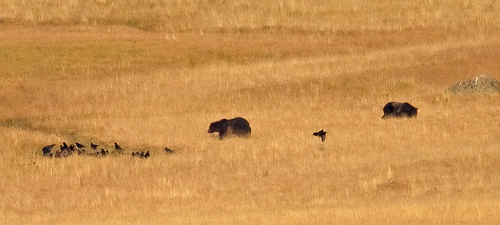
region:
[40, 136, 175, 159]
a flock of birds in a field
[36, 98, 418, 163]
bears chasing birds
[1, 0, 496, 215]
a field of brown grass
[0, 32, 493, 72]
grass is cut lower in this area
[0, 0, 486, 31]
grass is high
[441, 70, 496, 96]
a small pile of rocks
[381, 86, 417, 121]
bear is headed to the right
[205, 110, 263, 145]
bear is headed toward the birds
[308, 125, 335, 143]
bird flying away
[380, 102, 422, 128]
bear in the field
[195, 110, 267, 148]
bear in the field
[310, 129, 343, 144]
the bird is flying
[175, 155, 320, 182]
hay in the field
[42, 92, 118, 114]
weeds in the field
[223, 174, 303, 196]
he weeds are tall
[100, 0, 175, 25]
the weeds are tall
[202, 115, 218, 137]
head of the bear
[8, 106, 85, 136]
grass in the field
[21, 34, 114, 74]
grassy patch on field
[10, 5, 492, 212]
a photo during the day time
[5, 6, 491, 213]
a scene of a mostly dry grassy field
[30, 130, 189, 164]
a group of black birds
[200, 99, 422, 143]
a couple of black bears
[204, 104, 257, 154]
a bear walking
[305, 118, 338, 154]
a bird opening its wings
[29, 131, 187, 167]
some birds enjoying the day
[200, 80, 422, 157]
a couple of bears enjoying the day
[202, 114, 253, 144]
brown bear in a wheat field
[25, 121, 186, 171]
a flock of black birds on the ground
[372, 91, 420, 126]
brown bear walking on a field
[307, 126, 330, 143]
black bird flying close to the ground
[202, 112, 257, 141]
a grizzly bear walking on a field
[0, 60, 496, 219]
large field of gold grass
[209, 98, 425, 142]
two brown bears walking in opposite directions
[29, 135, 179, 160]
the flock of birds are eating something on the ground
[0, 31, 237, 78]
area of flat laying greener grass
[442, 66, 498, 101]
low laying rock in the field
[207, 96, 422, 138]
two black bears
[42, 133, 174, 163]
flock of black birds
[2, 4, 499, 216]
dry grass pasture bears are in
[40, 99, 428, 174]
bears and birds in a field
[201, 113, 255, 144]
bear walking towards the birds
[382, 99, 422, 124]
bear walking away from the birds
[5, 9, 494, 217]
expanse of dry brown grass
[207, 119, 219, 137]
head of bear closest to the birds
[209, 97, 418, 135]
furry bodies of the black bears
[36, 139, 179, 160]
black birds gathered in a field